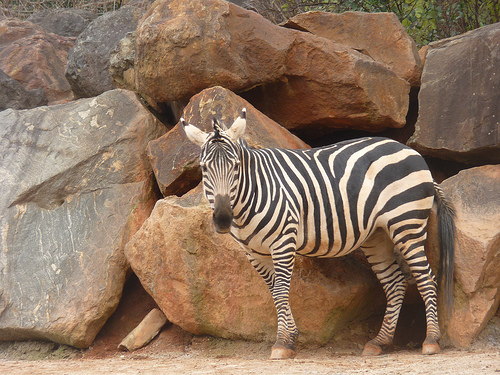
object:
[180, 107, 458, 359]
zebra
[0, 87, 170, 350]
rock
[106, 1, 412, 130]
rock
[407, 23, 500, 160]
rock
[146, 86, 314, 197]
rock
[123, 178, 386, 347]
rock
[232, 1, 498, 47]
trees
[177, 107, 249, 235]
head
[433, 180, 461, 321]
tail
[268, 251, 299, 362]
part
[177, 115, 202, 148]
part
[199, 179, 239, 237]
part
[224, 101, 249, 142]
part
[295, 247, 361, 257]
edge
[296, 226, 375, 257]
tummy